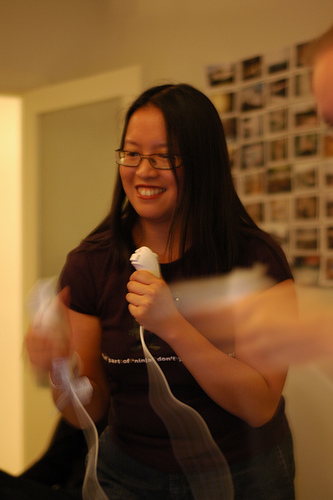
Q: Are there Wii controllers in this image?
A: Yes, there is a Wii controller.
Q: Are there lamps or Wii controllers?
A: Yes, there is a Wii controller.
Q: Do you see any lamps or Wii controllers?
A: Yes, there is a Wii controller.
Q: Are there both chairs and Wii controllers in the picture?
A: No, there is a Wii controller but no chairs.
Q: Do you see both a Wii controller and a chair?
A: No, there is a Wii controller but no chairs.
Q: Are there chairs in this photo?
A: No, there are no chairs.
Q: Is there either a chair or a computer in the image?
A: No, there are no chairs or computers.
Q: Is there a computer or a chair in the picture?
A: No, there are no chairs or computers.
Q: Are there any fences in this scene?
A: No, there are no fences.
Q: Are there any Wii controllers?
A: Yes, there is a Wii controller.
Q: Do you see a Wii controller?
A: Yes, there is a Wii controller.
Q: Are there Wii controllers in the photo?
A: Yes, there is a Wii controller.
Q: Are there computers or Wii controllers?
A: Yes, there is a Wii controller.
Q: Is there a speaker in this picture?
A: No, there are no speakers.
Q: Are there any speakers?
A: No, there are no speakers.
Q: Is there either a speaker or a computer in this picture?
A: No, there are no speakers or computers.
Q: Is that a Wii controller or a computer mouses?
A: That is a Wii controller.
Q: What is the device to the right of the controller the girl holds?
A: The device is a Wii controller.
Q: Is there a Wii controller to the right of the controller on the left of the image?
A: Yes, there is a Wii controller to the right of the controller.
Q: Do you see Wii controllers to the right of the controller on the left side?
A: Yes, there is a Wii controller to the right of the controller.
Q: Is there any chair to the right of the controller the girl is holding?
A: No, there is a Wii controller to the right of the controller.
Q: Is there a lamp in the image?
A: No, there are no lamps.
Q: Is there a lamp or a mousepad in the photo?
A: No, there are no lamps or mouse pads.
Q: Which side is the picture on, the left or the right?
A: The picture is on the right of the image.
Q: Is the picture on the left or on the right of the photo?
A: The picture is on the right of the image.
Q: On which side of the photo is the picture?
A: The picture is on the right of the image.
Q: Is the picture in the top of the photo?
A: Yes, the picture is in the top of the image.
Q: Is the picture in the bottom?
A: No, the picture is in the top of the image.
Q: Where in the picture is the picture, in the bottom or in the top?
A: The picture is in the top of the image.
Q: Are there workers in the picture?
A: No, there are no workers.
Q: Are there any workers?
A: No, there are no workers.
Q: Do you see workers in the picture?
A: No, there are no workers.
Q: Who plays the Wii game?
A: The girl plays the Wii game.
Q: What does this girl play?
A: The girl plays the Wii game.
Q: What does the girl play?
A: The girl plays the Wii game.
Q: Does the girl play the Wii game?
A: Yes, the girl plays the Wii game.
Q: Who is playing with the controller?
A: The girl is playing with the controller.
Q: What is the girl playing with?
A: The girl is playing with a controller.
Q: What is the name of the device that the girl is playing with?
A: The device is a controller.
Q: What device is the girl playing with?
A: The girl is playing with a controller.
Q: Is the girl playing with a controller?
A: Yes, the girl is playing with a controller.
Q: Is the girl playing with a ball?
A: No, the girl is playing with a controller.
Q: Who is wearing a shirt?
A: The girl is wearing a shirt.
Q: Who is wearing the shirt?
A: The girl is wearing a shirt.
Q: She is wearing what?
A: The girl is wearing a shirt.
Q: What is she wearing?
A: The girl is wearing a shirt.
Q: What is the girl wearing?
A: The girl is wearing a shirt.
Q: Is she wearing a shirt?
A: Yes, the girl is wearing a shirt.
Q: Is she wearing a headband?
A: No, the girl is wearing a shirt.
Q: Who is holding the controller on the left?
A: The girl is holding the controller.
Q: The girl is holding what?
A: The girl is holding the controller.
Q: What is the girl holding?
A: The girl is holding the controller.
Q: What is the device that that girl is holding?
A: The device is a controller.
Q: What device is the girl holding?
A: The girl is holding the controller.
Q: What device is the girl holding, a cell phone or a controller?
A: The girl is holding a controller.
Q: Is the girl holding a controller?
A: Yes, the girl is holding a controller.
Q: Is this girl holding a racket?
A: No, the girl is holding a controller.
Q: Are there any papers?
A: No, there are no papers.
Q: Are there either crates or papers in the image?
A: No, there are no papers or crates.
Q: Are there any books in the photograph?
A: No, there are no books.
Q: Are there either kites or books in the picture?
A: No, there are no books or kites.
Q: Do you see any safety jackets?
A: No, there are no safety jackets.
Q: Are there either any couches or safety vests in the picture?
A: No, there are no safety vests or couches.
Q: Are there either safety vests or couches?
A: No, there are no safety vests or couches.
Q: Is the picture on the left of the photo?
A: No, the picture is on the right of the image.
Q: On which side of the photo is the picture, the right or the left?
A: The picture is on the right of the image.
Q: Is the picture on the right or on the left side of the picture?
A: The picture is on the right of the image.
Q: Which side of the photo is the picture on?
A: The picture is on the right of the image.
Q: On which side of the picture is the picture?
A: The picture is on the right of the image.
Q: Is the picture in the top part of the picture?
A: Yes, the picture is in the top of the image.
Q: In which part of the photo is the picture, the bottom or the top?
A: The picture is in the top of the image.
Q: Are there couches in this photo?
A: No, there are no couches.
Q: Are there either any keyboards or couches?
A: No, there are no couches or keyboards.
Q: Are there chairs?
A: No, there are no chairs.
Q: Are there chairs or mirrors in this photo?
A: No, there are no chairs or mirrors.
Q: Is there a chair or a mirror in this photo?
A: No, there are no chairs or mirrors.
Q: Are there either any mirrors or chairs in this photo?
A: No, there are no chairs or mirrors.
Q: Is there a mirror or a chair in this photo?
A: No, there are no chairs or mirrors.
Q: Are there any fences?
A: No, there are no fences.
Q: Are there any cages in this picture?
A: No, there are no cages.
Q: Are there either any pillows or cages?
A: No, there are no cages or pillows.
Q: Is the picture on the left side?
A: No, the picture is on the right of the image.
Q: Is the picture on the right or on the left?
A: The picture is on the right of the image.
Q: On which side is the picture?
A: The picture is on the right of the image.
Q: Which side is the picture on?
A: The picture is on the right of the image.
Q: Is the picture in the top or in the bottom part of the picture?
A: The picture is in the top of the image.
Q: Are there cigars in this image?
A: No, there are no cigars.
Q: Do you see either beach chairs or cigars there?
A: No, there are no cigars or beach chairs.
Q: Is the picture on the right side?
A: Yes, the picture is on the right of the image.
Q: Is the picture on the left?
A: No, the picture is on the right of the image.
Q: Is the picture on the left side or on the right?
A: The picture is on the right of the image.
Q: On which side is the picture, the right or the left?
A: The picture is on the right of the image.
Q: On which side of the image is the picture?
A: The picture is on the right of the image.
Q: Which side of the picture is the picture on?
A: The picture is on the right of the image.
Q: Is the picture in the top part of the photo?
A: Yes, the picture is in the top of the image.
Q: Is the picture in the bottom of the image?
A: No, the picture is in the top of the image.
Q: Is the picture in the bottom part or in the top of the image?
A: The picture is in the top of the image.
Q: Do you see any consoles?
A: No, there are no consoles.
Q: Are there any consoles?
A: No, there are no consoles.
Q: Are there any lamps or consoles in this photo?
A: No, there are no consoles or lamps.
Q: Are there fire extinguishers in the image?
A: No, there are no fire extinguishers.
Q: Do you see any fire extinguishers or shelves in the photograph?
A: No, there are no fire extinguishers or shelves.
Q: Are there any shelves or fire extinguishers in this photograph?
A: No, there are no fire extinguishers or shelves.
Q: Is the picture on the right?
A: Yes, the picture is on the right of the image.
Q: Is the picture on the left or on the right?
A: The picture is on the right of the image.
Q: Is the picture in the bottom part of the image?
A: No, the picture is in the top of the image.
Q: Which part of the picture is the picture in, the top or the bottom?
A: The picture is in the top of the image.